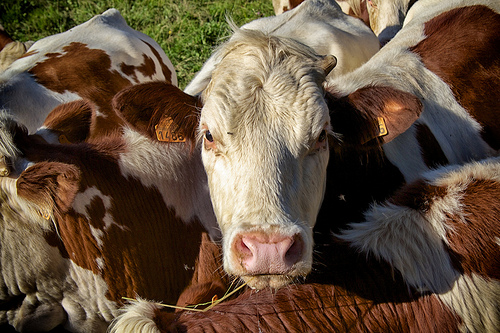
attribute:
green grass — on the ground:
[1, 0, 273, 58]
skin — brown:
[21, 38, 130, 126]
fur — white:
[196, 12, 331, 292]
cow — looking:
[110, 0, 485, 291]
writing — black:
[157, 128, 184, 142]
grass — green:
[1, 0, 273, 88]